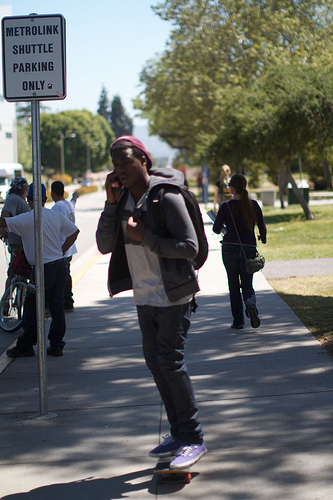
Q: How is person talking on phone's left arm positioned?
A: Bent.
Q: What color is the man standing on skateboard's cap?
A: Red.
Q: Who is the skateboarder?
A: Young man.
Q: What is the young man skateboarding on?
A: Sidewalk.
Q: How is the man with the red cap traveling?
A: By skateboard.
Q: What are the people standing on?
A: Sidewalk.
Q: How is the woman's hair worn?
A: In a ponytail.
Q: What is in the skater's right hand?
A: Cell phone.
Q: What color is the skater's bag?
A: Black.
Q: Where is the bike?
A: By the group of men near the curb.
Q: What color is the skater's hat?
A: Maroon.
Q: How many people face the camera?
A: Two.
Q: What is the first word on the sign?
A: METROLINK.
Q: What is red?
A: Boy's hat.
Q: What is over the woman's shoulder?
A: A purse.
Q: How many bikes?
A: One.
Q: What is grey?
A: A jacket.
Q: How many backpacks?
A: One.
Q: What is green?
A: Trees.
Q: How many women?
A: Two.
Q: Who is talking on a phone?
A: The man in the foreground.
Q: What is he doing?
A: Skateboarding.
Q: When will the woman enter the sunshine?
A: A few steps forward.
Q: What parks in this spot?
A: The Metrolink Shuttle.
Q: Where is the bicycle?
A: In the street.